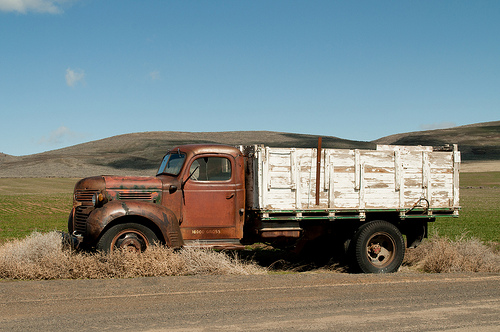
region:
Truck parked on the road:
[55, 93, 472, 280]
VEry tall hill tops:
[17, 89, 499, 155]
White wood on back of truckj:
[247, 125, 466, 225]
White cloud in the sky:
[57, 56, 99, 111]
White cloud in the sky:
[140, 53, 170, 84]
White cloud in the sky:
[16, 121, 91, 146]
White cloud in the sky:
[0, 6, 90, 23]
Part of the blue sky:
[368, 64, 435, 114]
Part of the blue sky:
[447, 60, 489, 108]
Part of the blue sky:
[436, 5, 484, 65]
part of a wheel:
[392, 235, 402, 248]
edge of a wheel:
[373, 213, 386, 233]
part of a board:
[316, 170, 333, 200]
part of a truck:
[302, 163, 304, 167]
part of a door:
[185, 219, 200, 236]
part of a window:
[208, 162, 225, 181]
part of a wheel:
[358, 235, 364, 261]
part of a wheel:
[382, 238, 398, 254]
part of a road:
[327, 285, 338, 310]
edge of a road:
[240, 232, 270, 302]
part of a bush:
[191, 255, 203, 274]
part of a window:
[191, 180, 206, 182]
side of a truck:
[298, 212, 321, 259]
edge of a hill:
[113, 142, 128, 164]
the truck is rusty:
[66, 126, 247, 290]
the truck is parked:
[52, 87, 478, 309]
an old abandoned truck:
[0, 5, 496, 325]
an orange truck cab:
[77, 141, 243, 236]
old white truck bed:
[245, 130, 480, 220]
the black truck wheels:
[335, 225, 415, 270]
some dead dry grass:
[7, 235, 63, 265]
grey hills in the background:
[60, 106, 332, 141]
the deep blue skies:
[1, 0, 491, 115]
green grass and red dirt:
[0, 180, 55, 225]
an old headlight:
[85, 180, 110, 210]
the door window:
[190, 156, 231, 179]